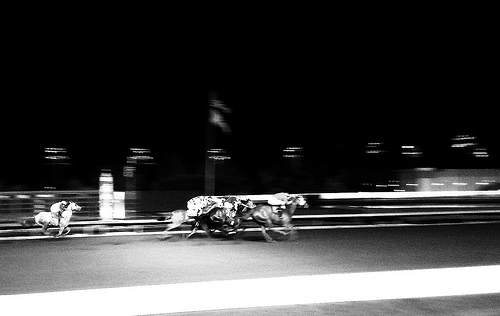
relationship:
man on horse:
[215, 195, 236, 236] [158, 178, 256, 250]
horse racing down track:
[19, 201, 82, 238] [0, 215, 499, 314]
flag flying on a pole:
[209, 109, 232, 132] [201, 89, 226, 201]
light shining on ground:
[5, 264, 499, 313] [0, 217, 500, 313]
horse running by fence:
[19, 201, 82, 238] [0, 259, 498, 315]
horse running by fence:
[156, 197, 256, 241] [0, 259, 498, 315]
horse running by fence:
[239, 197, 254, 219] [0, 259, 498, 315]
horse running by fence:
[241, 192, 310, 243] [0, 259, 498, 315]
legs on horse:
[252, 216, 298, 247] [244, 191, 310, 246]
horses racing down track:
[22, 186, 308, 241] [0, 215, 499, 314]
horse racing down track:
[241, 192, 310, 243] [0, 215, 499, 314]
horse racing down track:
[156, 197, 256, 241] [0, 215, 499, 314]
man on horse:
[50, 201, 67, 219] [19, 198, 82, 238]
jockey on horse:
[266, 188, 290, 206] [205, 199, 252, 238]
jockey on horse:
[222, 192, 239, 206] [242, 194, 308, 239]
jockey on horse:
[161, 196, 256, 240] [155, 207, 194, 236]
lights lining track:
[3, 94, 499, 222] [0, 215, 499, 314]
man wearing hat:
[50, 201, 67, 219] [64, 200, 69, 205]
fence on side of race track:
[0, 189, 212, 226] [5, 68, 497, 314]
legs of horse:
[254, 223, 296, 243] [174, 184, 324, 238]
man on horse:
[219, 195, 255, 227] [182, 192, 257, 240]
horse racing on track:
[241, 192, 310, 243] [0, 215, 499, 314]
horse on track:
[162, 192, 239, 239] [6, 202, 496, 308]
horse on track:
[242, 182, 317, 237] [6, 202, 496, 308]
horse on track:
[19, 201, 82, 238] [6, 202, 496, 308]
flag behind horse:
[211, 113, 227, 130] [197, 210, 257, 244]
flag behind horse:
[210, 96, 232, 117] [253, 209, 294, 239]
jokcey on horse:
[50, 200, 70, 212] [36, 204, 81, 235]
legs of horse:
[55, 221, 66, 236] [33, 197, 84, 252]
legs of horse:
[36, 221, 83, 245] [30, 211, 82, 239]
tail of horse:
[13, 213, 35, 229] [18, 198, 75, 231]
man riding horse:
[45, 198, 70, 215] [24, 189, 91, 242]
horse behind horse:
[241, 192, 310, 243] [156, 197, 256, 241]